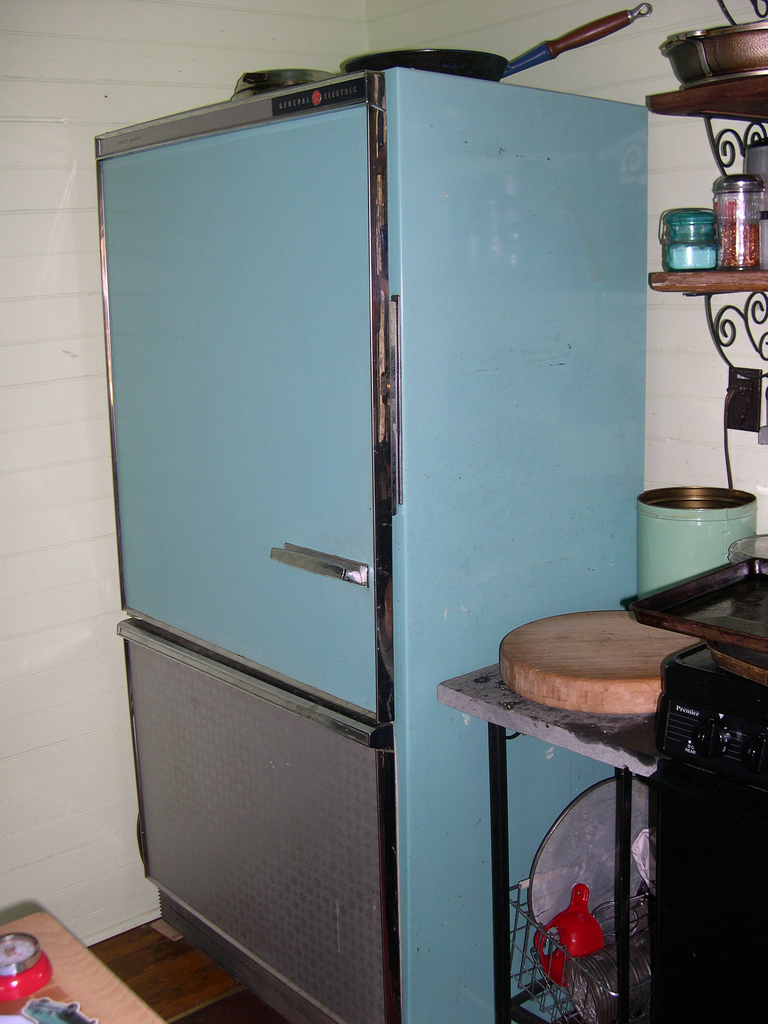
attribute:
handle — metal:
[264, 535, 372, 593]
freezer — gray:
[117, 618, 402, 1022]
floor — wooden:
[88, 918, 284, 1023]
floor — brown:
[85, 912, 293, 1022]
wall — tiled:
[2, 1, 767, 947]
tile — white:
[0, 535, 120, 603]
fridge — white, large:
[91, 62, 651, 1023]